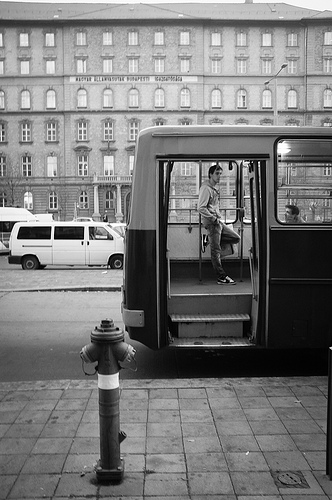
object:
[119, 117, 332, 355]
bus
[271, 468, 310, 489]
square iron gate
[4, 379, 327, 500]
ground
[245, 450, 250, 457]
small piece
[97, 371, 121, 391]
is white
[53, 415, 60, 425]
black spot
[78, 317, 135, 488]
fire hydrant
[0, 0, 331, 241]
apartment building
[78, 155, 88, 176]
large window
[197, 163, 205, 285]
post on bus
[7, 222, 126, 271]
large white van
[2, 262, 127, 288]
in spot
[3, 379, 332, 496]
sidewalk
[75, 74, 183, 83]
it's name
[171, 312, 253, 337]
steps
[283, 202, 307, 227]
man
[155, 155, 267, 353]
door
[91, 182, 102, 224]
big pillars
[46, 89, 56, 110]
windows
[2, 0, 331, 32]
roof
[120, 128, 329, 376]
bus stop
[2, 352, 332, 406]
beside the bus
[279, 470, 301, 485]
drain hole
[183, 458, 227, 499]
cement tiles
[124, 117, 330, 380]
waiting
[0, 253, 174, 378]
city street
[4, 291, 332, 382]
paved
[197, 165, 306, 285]
talking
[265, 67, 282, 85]
light pole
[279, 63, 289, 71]
light on it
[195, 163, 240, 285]
man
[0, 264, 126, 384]
road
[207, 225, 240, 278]
wearing jeans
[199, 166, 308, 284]
two men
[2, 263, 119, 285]
side of the road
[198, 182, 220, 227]
sweatshirt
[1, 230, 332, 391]
two lanes